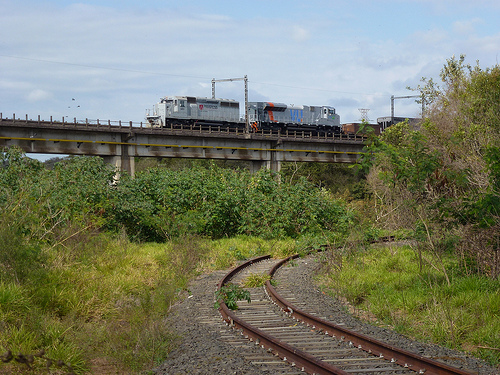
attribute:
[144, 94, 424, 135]
train — silver, white, gray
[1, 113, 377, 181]
bridge — concrete, elevated, rusted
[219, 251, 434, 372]
railroad track — rusty, brown, curved, overgrown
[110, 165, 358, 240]
bushes — green, leafy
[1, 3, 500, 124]
sky — blue